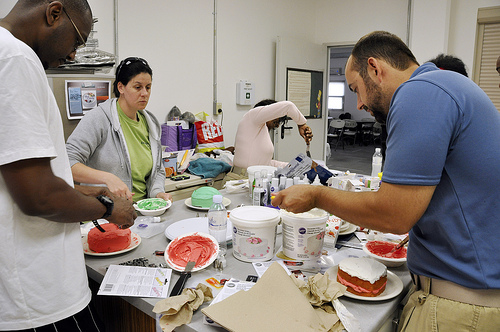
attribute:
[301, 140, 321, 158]
knife — decorating 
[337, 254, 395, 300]
cake —  white 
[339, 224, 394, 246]
frosting — red 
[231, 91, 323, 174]
woman — putting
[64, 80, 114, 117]
small poster — hanging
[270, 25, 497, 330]
man — light 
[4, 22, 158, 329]
shirt — white 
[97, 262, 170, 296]
paper — white 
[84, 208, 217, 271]
red cake — red , white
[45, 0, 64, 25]
ear — handles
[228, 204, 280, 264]
bucket — cake frosting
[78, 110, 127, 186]
jacket — gray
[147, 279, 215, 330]
napkin — tan 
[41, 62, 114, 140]
board — bulletin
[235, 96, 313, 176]
shirt — pink 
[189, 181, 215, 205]
icing — green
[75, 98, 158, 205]
shirt. — green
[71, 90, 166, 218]
jacket — gray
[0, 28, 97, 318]
shirt. — white